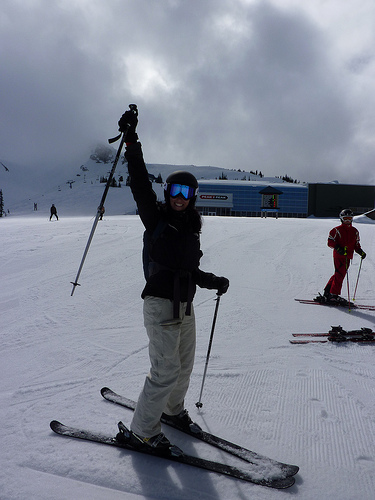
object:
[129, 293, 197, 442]
pants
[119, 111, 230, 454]
woman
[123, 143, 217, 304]
jacket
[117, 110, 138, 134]
glove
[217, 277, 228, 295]
glove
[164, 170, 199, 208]
helmet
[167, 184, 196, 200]
goggles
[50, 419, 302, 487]
skis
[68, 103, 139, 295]
ski pole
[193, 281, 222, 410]
ski pole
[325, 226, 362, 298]
outfit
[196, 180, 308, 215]
building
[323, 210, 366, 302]
man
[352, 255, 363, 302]
ski poles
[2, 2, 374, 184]
clouds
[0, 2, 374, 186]
sky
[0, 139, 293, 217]
mountain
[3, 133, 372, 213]
background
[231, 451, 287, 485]
snow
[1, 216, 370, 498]
ice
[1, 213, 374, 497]
ground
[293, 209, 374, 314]
ice skating